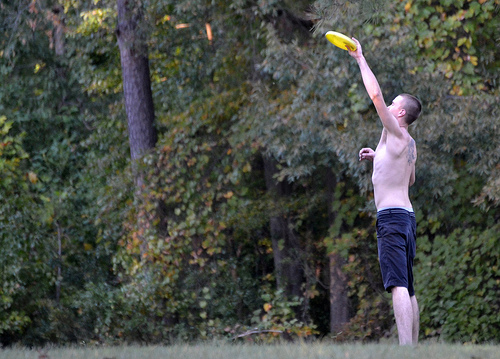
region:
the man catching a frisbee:
[313, 13, 443, 335]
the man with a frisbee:
[307, 20, 447, 346]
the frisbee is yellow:
[313, 21, 463, 343]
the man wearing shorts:
[316, 19, 441, 354]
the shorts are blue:
[318, 21, 455, 346]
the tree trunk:
[108, 49, 163, 150]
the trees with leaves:
[150, 2, 318, 322]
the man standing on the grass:
[317, 19, 434, 356]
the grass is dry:
[89, 347, 404, 357]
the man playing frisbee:
[303, 20, 448, 338]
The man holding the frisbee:
[347, 36, 426, 347]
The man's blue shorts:
[367, 205, 420, 298]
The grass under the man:
[0, 335, 498, 357]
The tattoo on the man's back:
[398, 131, 419, 168]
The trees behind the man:
[0, 0, 495, 341]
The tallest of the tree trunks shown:
[103, 3, 158, 270]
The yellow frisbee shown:
[323, 28, 359, 54]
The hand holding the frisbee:
[343, 34, 363, 59]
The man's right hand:
[355, 141, 375, 162]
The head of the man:
[385, 87, 430, 134]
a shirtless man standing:
[343, 37, 423, 349]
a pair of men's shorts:
[367, 205, 417, 296]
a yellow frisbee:
[321, 25, 356, 55]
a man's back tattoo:
[406, 126, 418, 168]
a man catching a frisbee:
[324, 20, 426, 345]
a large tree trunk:
[109, 5, 154, 180]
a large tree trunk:
[266, 163, 317, 320]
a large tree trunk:
[326, 246, 349, 341]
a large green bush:
[411, 224, 495, 339]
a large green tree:
[121, 102, 325, 320]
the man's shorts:
[375, 205, 422, 296]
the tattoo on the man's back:
[403, 136, 416, 166]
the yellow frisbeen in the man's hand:
[323, 30, 355, 54]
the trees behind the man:
[19, 13, 451, 330]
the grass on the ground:
[19, 331, 436, 357]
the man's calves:
[382, 284, 422, 345]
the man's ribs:
[368, 154, 394, 193]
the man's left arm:
[337, 32, 406, 137]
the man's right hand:
[355, 142, 375, 162]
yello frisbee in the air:
[320, 16, 368, 66]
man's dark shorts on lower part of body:
[352, 198, 462, 295]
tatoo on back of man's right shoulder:
[401, 127, 426, 183]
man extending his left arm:
[346, 33, 401, 130]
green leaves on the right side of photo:
[433, 226, 493, 324]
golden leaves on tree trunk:
[115, 201, 187, 273]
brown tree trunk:
[122, 61, 170, 150]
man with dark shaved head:
[403, 95, 434, 133]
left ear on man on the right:
[396, 100, 416, 127]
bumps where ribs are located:
[366, 159, 391, 199]